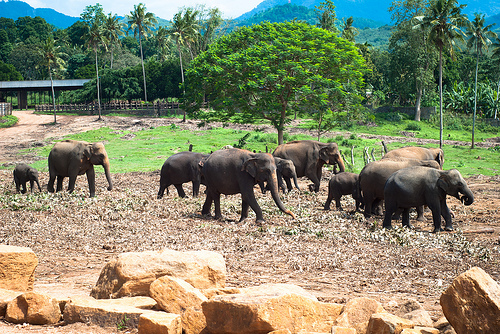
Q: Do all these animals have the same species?
A: Yes, all the animals are elephants.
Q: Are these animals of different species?
A: No, all the animals are elephants.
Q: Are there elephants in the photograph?
A: Yes, there is an elephant.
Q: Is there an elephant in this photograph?
A: Yes, there is an elephant.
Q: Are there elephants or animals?
A: Yes, there is an elephant.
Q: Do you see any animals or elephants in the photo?
A: Yes, there is an elephant.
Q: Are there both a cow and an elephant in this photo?
A: No, there is an elephant but no cows.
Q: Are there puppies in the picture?
A: No, there are no puppies.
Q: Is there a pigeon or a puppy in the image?
A: No, there are no puppies or pigeons.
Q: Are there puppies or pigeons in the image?
A: No, there are no puppies or pigeons.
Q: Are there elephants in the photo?
A: Yes, there is an elephant.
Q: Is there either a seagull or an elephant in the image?
A: Yes, there is an elephant.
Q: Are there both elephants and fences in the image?
A: Yes, there are both an elephant and a fence.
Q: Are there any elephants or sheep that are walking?
A: Yes, the elephant is walking.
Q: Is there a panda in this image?
A: No, there are no pandas.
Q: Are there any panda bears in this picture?
A: No, there are no panda bears.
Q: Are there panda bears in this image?
A: No, there are no panda bears.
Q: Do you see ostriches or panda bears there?
A: No, there are no panda bears or ostriches.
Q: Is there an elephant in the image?
A: Yes, there is an elephant.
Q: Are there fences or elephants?
A: Yes, there is an elephant.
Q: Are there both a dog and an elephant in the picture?
A: No, there is an elephant but no dogs.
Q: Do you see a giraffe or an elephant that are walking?
A: Yes, the elephant is walking.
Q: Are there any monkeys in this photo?
A: No, there are no monkeys.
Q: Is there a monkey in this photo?
A: No, there are no monkeys.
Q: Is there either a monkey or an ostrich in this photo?
A: No, there are no monkeys or ostriches.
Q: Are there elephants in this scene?
A: Yes, there is an elephant.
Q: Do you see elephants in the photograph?
A: Yes, there is an elephant.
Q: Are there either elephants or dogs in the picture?
A: Yes, there is an elephant.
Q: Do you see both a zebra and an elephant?
A: No, there is an elephant but no zebras.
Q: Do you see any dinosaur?
A: No, there are no dinosaurs.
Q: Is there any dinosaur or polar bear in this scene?
A: No, there are no dinosaurs or polar bears.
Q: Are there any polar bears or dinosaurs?
A: No, there are no dinosaurs or polar bears.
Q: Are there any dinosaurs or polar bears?
A: No, there are no dinosaurs or polar bears.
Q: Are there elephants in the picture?
A: Yes, there is an elephant.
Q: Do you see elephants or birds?
A: Yes, there is an elephant.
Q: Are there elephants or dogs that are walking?
A: Yes, the elephant is walking.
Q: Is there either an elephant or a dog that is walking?
A: Yes, the elephant is walking.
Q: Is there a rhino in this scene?
A: No, there are no rhinos.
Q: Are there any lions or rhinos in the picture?
A: No, there are no rhinos or lions.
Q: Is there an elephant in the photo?
A: Yes, there is an elephant.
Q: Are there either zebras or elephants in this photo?
A: Yes, there is an elephant.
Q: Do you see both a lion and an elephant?
A: No, there is an elephant but no lions.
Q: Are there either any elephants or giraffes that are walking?
A: Yes, the elephant is walking.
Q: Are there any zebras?
A: No, there are no zebras.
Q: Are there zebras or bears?
A: No, there are no zebras or bears.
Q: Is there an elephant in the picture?
A: Yes, there is an elephant.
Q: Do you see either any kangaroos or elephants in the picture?
A: Yes, there is an elephant.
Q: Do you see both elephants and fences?
A: Yes, there are both an elephant and a fence.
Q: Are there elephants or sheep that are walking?
A: Yes, the elephant is walking.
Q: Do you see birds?
A: No, there are no birds.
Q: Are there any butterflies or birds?
A: No, there are no birds or butterflies.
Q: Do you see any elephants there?
A: Yes, there is an elephant.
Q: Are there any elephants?
A: Yes, there is an elephant.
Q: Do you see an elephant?
A: Yes, there is an elephant.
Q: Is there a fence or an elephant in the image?
A: Yes, there is an elephant.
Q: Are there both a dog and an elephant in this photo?
A: No, there is an elephant but no dogs.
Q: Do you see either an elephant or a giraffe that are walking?
A: Yes, the elephant is walking.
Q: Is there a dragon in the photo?
A: No, there are no dragons.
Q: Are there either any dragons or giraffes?
A: No, there are no dragons or giraffes.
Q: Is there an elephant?
A: Yes, there is an elephant.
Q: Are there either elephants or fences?
A: Yes, there is an elephant.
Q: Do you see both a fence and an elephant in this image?
A: Yes, there are both an elephant and a fence.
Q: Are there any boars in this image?
A: No, there are no boars.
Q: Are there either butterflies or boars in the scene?
A: No, there are no boars or butterflies.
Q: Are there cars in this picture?
A: No, there are no cars.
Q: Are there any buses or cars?
A: No, there are no cars or buses.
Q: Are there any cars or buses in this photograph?
A: No, there are no cars or buses.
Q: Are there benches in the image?
A: No, there are no benches.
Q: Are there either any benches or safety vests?
A: No, there are no benches or safety vests.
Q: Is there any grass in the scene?
A: Yes, there is grass.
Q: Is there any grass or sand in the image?
A: Yes, there is grass.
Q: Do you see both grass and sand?
A: No, there is grass but no sand.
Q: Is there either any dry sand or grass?
A: Yes, there is dry grass.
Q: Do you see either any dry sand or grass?
A: Yes, there is dry grass.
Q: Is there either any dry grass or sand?
A: Yes, there is dry grass.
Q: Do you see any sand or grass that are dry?
A: Yes, the grass is dry.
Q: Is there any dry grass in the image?
A: Yes, there is dry grass.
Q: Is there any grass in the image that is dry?
A: Yes, there is grass that is dry.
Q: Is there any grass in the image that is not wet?
A: Yes, there is dry grass.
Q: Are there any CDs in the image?
A: No, there are no cds.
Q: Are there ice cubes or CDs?
A: No, there are no CDs or ice cubes.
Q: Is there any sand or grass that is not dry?
A: No, there is grass but it is dry.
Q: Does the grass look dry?
A: Yes, the grass is dry.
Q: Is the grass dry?
A: Yes, the grass is dry.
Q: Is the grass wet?
A: No, the grass is dry.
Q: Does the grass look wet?
A: No, the grass is dry.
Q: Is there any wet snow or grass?
A: No, there is grass but it is dry.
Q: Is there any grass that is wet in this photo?
A: No, there is grass but it is dry.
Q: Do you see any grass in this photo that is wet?
A: No, there is grass but it is dry.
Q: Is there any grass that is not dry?
A: No, there is grass but it is dry.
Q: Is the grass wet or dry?
A: The grass is dry.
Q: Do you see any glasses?
A: No, there are no glasses.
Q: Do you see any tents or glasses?
A: No, there are no glasses or tents.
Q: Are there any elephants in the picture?
A: Yes, there is an elephant.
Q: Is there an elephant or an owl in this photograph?
A: Yes, there is an elephant.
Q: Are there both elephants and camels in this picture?
A: No, there is an elephant but no camels.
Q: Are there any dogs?
A: No, there are no dogs.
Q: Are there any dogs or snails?
A: No, there are no dogs or snails.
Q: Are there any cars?
A: No, there are no cars.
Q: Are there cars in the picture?
A: No, there are no cars.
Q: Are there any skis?
A: No, there are no skis.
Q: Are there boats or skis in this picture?
A: No, there are no skis or boats.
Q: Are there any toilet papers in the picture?
A: No, there are no toilet papers.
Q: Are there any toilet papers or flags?
A: No, there are no toilet papers or flags.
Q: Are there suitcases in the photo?
A: No, there are no suitcases.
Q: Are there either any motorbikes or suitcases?
A: No, there are no suitcases or motorbikes.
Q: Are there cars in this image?
A: No, there are no cars.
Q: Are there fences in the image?
A: Yes, there is a fence.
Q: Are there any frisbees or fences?
A: Yes, there is a fence.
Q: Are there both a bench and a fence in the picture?
A: No, there is a fence but no benches.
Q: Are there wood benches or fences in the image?
A: Yes, there is a wood fence.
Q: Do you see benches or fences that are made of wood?
A: Yes, the fence is made of wood.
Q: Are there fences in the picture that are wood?
A: Yes, there is a wood fence.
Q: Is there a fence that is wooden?
A: Yes, there is a fence that is wooden.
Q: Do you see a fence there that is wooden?
A: Yes, there is a fence that is wooden.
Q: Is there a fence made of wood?
A: Yes, there is a fence that is made of wood.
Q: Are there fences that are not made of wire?
A: Yes, there is a fence that is made of wood.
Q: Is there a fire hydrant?
A: No, there are no fire hydrants.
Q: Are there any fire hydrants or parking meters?
A: No, there are no fire hydrants or parking meters.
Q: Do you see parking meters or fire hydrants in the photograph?
A: No, there are no fire hydrants or parking meters.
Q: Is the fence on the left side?
A: Yes, the fence is on the left of the image.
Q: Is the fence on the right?
A: No, the fence is on the left of the image.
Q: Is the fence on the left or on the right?
A: The fence is on the left of the image.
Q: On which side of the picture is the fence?
A: The fence is on the left of the image.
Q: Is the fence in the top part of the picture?
A: Yes, the fence is in the top of the image.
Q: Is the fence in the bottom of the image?
A: No, the fence is in the top of the image.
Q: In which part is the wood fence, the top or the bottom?
A: The fence is in the top of the image.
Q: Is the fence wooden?
A: Yes, the fence is wooden.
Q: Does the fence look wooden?
A: Yes, the fence is wooden.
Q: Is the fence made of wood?
A: Yes, the fence is made of wood.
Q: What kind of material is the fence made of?
A: The fence is made of wood.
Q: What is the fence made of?
A: The fence is made of wood.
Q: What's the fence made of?
A: The fence is made of wood.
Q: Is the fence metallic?
A: No, the fence is wooden.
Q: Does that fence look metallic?
A: No, the fence is wooden.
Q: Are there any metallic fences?
A: No, there is a fence but it is wooden.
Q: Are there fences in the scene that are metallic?
A: No, there is a fence but it is wooden.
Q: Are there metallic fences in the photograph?
A: No, there is a fence but it is wooden.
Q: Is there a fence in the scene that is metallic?
A: No, there is a fence but it is wooden.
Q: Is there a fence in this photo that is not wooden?
A: No, there is a fence but it is wooden.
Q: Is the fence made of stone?
A: No, the fence is made of wood.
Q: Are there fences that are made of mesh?
A: No, there is a fence but it is made of wood.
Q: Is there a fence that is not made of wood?
A: No, there is a fence but it is made of wood.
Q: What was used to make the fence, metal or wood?
A: The fence is made of wood.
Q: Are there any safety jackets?
A: No, there are no safety jackets.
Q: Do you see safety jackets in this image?
A: No, there are no safety jackets.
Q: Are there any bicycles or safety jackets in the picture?
A: No, there are no safety jackets or bicycles.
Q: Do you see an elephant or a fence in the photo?
A: Yes, there is an elephant.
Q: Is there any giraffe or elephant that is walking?
A: Yes, the elephant is walking.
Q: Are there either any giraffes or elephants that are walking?
A: Yes, the elephant is walking.